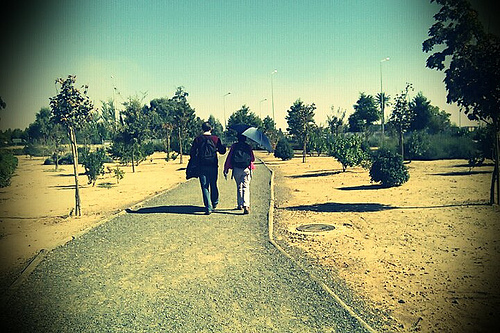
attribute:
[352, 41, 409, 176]
pole — light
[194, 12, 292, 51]
sky — blue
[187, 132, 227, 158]
backpack — black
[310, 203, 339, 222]
sand — covered, sidewalk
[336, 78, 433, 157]
tree — various, thin, skinny, beside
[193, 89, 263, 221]
couple — walking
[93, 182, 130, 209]
gravel — scattered, path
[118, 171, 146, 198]
dirt — brown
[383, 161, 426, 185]
shrub — green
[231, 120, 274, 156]
umbrella — black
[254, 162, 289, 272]
edge — wooden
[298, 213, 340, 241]
hole — cover, man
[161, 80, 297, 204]
people — walking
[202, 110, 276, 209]
person — holding, walking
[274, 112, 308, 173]
bush — small, green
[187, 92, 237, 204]
man — walking, carrying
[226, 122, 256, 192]
woman — carrying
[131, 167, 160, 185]
soil — brown